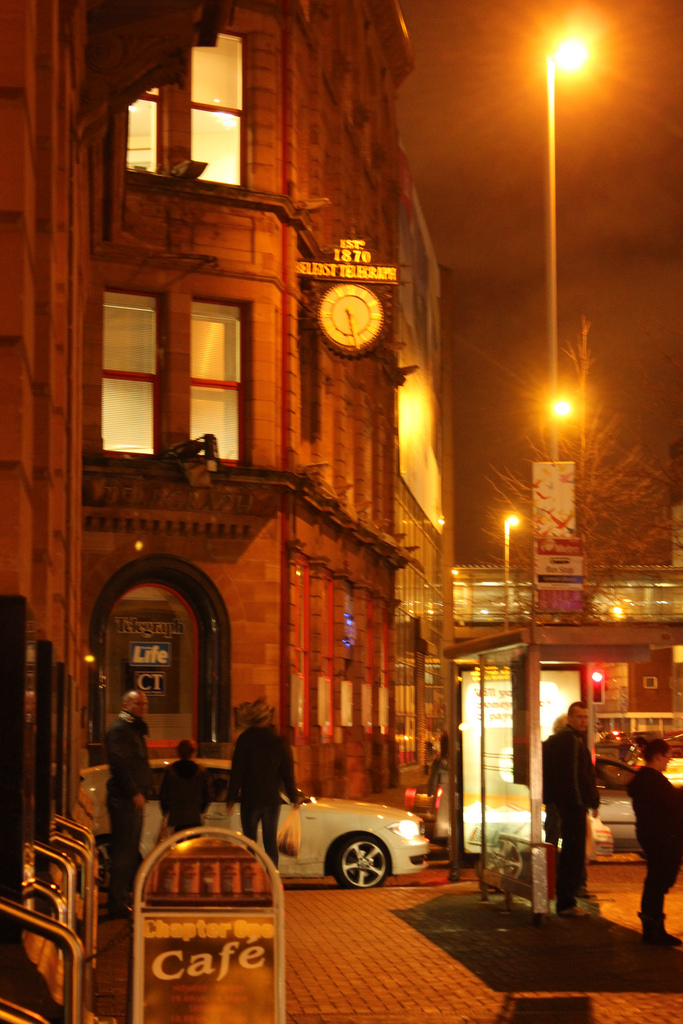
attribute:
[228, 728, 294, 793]
jacket — black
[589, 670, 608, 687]
trafficlight — red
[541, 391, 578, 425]
streetlights — bright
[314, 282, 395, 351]
clock — white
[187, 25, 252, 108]
window — glass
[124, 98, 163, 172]
window — glass